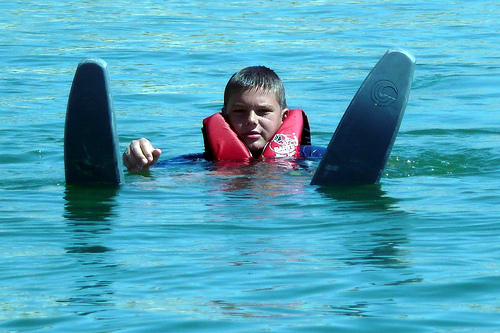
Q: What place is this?
A: It is an ocean.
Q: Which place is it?
A: It is an ocean.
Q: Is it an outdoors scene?
A: Yes, it is outdoors.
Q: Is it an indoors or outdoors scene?
A: It is outdoors.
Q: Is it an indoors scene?
A: No, it is outdoors.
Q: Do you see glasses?
A: No, there are no glasses.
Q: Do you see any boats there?
A: No, there are no boats.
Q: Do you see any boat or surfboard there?
A: No, there are no boats or surfboards.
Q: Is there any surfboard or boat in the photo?
A: No, there are no boats or surfboards.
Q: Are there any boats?
A: No, there are no boats.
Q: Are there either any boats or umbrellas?
A: No, there are no boats or umbrellas.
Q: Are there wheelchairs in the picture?
A: No, there are no wheelchairs.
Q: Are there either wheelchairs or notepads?
A: No, there are no wheelchairs or notepads.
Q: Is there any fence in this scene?
A: No, there are no fences.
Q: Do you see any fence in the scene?
A: No, there are no fences.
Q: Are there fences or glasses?
A: No, there are no fences or glasses.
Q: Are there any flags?
A: No, there are no flags.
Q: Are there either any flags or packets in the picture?
A: No, there are no flags or packets.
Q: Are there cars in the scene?
A: No, there are no cars.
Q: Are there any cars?
A: No, there are no cars.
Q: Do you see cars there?
A: No, there are no cars.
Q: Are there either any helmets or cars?
A: No, there are no cars or helmets.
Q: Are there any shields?
A: No, there are no shields.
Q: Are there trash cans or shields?
A: No, there are no shields or trash cans.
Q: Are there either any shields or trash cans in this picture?
A: No, there are no shields or trash cans.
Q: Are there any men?
A: No, there are no men.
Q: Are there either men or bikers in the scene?
A: No, there are no men or bikers.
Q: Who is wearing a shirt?
A: The boy is wearing a shirt.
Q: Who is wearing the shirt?
A: The boy is wearing a shirt.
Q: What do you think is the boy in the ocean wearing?
A: The boy is wearing a shirt.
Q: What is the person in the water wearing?
A: The boy is wearing a shirt.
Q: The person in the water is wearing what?
A: The boy is wearing a shirt.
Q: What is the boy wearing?
A: The boy is wearing a shirt.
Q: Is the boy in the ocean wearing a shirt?
A: Yes, the boy is wearing a shirt.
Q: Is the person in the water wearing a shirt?
A: Yes, the boy is wearing a shirt.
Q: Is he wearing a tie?
A: No, the boy is wearing a shirt.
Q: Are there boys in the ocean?
A: Yes, there is a boy in the ocean.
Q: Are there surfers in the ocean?
A: No, there is a boy in the ocean.